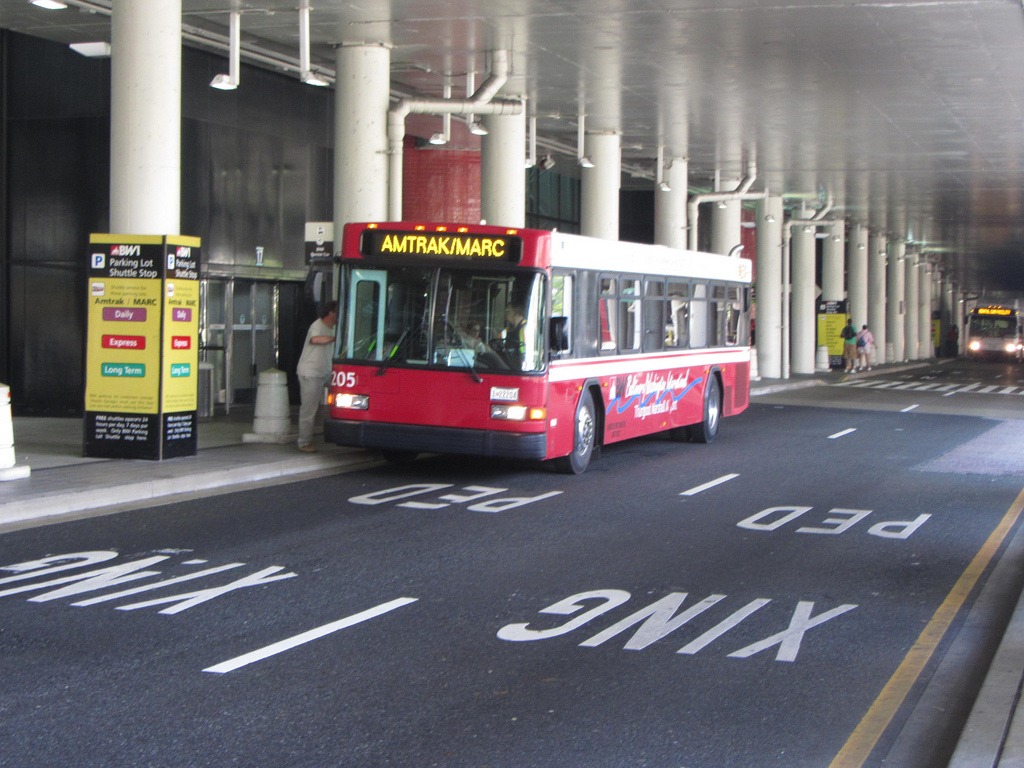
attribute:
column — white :
[105, 1, 186, 237]